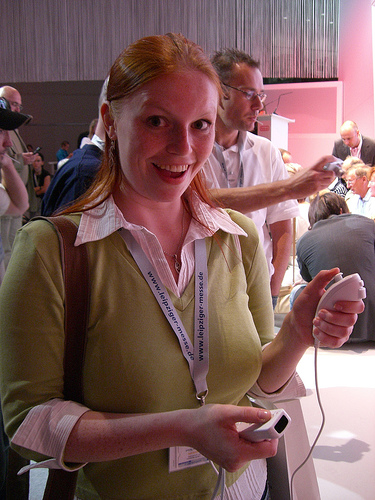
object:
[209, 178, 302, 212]
arm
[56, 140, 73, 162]
man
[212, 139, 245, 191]
gray lanyard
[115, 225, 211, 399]
gray lanyard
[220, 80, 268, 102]
glasses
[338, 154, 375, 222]
man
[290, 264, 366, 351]
woman hand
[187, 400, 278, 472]
woman hand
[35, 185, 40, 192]
woman hand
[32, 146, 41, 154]
cellphone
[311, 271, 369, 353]
controller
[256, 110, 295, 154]
white podium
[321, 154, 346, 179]
camera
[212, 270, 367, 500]
wii nunchuck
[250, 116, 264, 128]
toothpick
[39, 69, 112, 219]
man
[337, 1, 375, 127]
wall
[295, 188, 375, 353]
man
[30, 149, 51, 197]
man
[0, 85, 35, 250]
man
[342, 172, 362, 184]
glasses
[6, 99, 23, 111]
glasses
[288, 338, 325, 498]
cord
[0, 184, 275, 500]
sweater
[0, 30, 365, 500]
people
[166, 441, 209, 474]
name badge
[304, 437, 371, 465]
shadow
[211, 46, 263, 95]
hair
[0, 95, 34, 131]
cap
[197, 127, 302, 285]
shirt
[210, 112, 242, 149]
neck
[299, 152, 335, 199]
hand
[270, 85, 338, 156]
wall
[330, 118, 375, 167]
man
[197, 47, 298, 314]
man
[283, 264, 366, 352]
in hand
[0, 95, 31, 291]
man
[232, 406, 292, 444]
remote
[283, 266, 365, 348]
hand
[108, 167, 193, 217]
neck